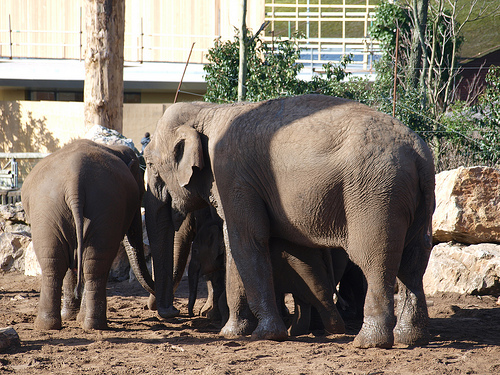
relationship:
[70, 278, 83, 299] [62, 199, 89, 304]
hair at end of tail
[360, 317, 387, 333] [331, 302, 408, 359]
marks on foot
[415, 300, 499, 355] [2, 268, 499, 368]
shadow on ground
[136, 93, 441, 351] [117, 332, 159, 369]
elephant on dirt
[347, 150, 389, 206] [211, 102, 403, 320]
lines on skin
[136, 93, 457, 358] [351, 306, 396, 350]
elephant has left foot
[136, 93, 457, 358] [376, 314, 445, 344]
elephant has foot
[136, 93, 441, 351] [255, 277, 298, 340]
elephant has foot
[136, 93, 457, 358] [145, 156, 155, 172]
elephant has eye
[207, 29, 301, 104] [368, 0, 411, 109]
tree behind tree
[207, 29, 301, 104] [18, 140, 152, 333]
tree behind elephant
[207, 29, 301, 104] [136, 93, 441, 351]
tree behind elephant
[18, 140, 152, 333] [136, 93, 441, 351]
elephant next to elephant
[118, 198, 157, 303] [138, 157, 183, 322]
trunk hanging towards trunk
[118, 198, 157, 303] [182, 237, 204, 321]
trunk hanging towards trunk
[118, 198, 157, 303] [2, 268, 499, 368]
trunk hanging towards ground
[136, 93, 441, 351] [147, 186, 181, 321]
elephant with trunk